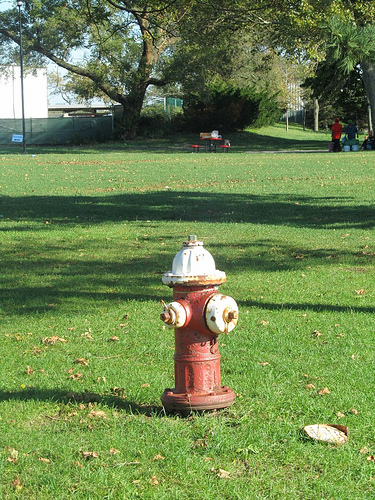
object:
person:
[346, 113, 360, 143]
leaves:
[34, 189, 364, 495]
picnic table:
[199, 132, 220, 154]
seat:
[188, 143, 200, 147]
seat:
[218, 144, 230, 149]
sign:
[8, 130, 28, 151]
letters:
[10, 130, 22, 138]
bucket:
[342, 144, 351, 152]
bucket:
[351, 143, 359, 151]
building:
[0, 63, 50, 121]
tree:
[1, 0, 375, 141]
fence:
[0, 114, 181, 149]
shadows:
[0, 176, 375, 308]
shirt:
[332, 122, 343, 140]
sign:
[12, 129, 24, 146]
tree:
[0, 2, 286, 144]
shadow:
[2, 188, 375, 326]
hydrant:
[160, 233, 240, 415]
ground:
[1, 121, 375, 497]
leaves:
[9, 319, 161, 479]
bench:
[191, 130, 233, 152]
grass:
[2, 124, 375, 499]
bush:
[164, 79, 281, 142]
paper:
[302, 420, 353, 445]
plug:
[204, 291, 242, 340]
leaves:
[24, 320, 164, 456]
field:
[0, 120, 374, 496]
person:
[329, 118, 343, 149]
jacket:
[330, 123, 342, 140]